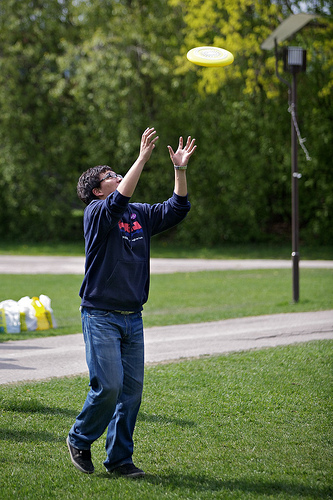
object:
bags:
[0, 297, 23, 337]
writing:
[117, 212, 146, 247]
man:
[65, 123, 199, 480]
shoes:
[63, 430, 97, 475]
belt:
[78, 302, 143, 315]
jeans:
[66, 303, 147, 468]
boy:
[64, 123, 198, 481]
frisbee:
[184, 44, 236, 69]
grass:
[0, 335, 333, 499]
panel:
[260, 5, 317, 94]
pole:
[289, 73, 301, 301]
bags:
[15, 294, 38, 332]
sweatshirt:
[78, 187, 192, 313]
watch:
[173, 165, 187, 171]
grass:
[0, 266, 333, 338]